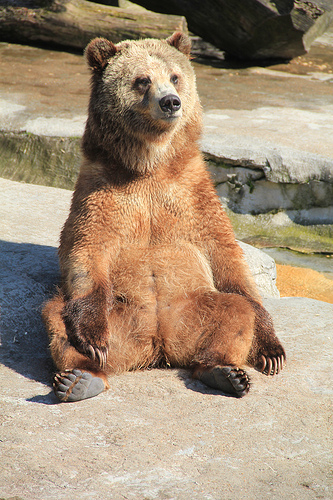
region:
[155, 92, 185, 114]
Black nose on bear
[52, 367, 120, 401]
Black foot pad on brown bear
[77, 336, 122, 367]
Brown bear claws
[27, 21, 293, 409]
Large brown bear sitting down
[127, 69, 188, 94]
Two black eyes on brown bear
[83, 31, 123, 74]
One brown ear on bear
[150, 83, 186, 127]
White muzzle on brown bear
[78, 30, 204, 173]
Brown head on brown bear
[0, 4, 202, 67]
Piece of brown log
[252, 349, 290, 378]
Five bear claws on bears paw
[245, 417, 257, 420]
part of the ground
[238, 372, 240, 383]
part of a foot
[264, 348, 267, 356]
part of an arm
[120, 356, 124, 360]
leg of a bear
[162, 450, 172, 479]
part of the floor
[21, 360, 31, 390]
part of a shadow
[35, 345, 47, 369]
edge of a shadow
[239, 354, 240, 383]
part of a finger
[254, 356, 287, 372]
claws on the bear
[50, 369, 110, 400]
paws on the bear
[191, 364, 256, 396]
paws on the bear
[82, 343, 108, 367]
claws on the bear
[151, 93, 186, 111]
nose on the bear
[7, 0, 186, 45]
logs on the rock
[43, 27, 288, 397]
bear sitting on a rock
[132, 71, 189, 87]
eyes on bear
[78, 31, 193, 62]
ears on the bear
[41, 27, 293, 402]
brown bear sitting on rock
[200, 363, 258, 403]
the bears foot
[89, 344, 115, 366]
the bears nails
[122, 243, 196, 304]
bears belly is brown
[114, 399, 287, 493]
the ground is grey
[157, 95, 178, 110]
nose is black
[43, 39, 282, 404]
the bear is sitting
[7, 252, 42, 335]
a shadow on the ground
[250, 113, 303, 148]
a rock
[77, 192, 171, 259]
the bears fur is brown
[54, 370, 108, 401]
the bears foot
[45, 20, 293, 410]
a bear in a zoo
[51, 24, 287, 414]
a bear sitting down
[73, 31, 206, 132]
the head of a bear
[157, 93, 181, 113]
the nose of a bear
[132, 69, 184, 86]
the eyes of a bear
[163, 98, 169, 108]
the nostril of a bear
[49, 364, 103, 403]
the foot of a bear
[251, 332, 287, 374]
the paw of a bear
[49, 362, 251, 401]
the rear feet of a bear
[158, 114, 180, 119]
the mouth of a bear